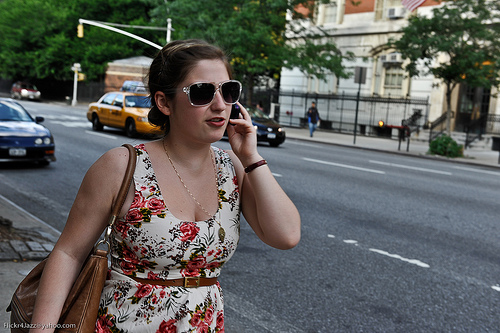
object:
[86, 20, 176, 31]
support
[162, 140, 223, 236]
necklace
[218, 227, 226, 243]
pendant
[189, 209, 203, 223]
cleavage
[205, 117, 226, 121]
lips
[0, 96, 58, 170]
automobile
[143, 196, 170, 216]
roses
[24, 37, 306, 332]
woman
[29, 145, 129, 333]
arm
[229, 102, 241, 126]
cell phone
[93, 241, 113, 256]
loop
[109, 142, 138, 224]
strap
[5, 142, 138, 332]
purse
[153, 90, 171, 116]
ear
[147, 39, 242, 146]
head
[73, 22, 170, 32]
pole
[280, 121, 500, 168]
sidewalk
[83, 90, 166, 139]
cab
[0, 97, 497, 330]
street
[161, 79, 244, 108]
sunglasses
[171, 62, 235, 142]
girl's face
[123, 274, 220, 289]
belt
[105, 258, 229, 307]
girl's waist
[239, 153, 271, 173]
girl's wrist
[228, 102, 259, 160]
hand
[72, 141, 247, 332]
dress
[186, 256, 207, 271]
flowers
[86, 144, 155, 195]
shoulder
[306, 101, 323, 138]
person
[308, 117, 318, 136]
pants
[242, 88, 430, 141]
fence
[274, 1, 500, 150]
building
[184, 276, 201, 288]
buckle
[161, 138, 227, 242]
chain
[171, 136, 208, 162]
neck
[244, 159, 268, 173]
watchband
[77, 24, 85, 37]
signal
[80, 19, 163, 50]
arm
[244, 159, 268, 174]
watch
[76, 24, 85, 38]
light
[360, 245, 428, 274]
line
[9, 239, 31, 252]
bricks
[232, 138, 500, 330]
ground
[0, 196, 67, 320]
sidewalk